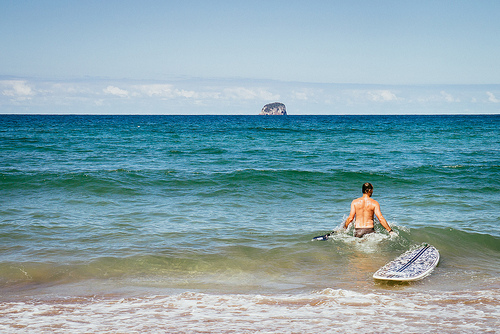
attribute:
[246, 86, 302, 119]
rock — large, on sea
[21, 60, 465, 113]
clouds — white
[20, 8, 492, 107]
sky — blue, clear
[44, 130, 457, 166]
waters — clam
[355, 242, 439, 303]
board — white, surfboard, wooden, beside man, in water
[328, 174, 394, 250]
man — walking, going to surf, on water, bare chested, wet, bald headed, in water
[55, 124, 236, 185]
waves — breaking, in ocean, small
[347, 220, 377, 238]
trunks — brown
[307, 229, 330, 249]
object — floating, blue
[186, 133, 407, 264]
water — green, blue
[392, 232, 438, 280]
stripes — black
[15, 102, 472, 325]
island — compact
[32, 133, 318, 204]
wave — small